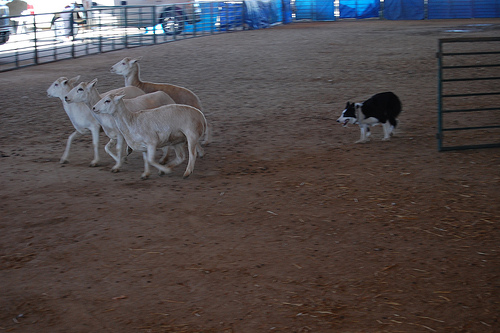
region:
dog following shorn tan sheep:
[40, 48, 405, 178]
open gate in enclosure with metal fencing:
[0, 0, 492, 155]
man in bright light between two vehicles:
[0, 0, 200, 70]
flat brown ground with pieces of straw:
[6, 15, 491, 322]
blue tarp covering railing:
[182, 0, 497, 35]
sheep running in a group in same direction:
[45, 50, 210, 175]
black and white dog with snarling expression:
[330, 85, 400, 145]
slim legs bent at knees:
[55, 126, 170, 177]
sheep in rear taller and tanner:
[45, 51, 206, 173]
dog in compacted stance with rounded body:
[335, 88, 403, 143]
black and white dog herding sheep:
[323, 86, 410, 153]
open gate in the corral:
[430, 29, 491, 114]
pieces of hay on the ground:
[336, 200, 405, 310]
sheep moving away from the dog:
[37, 51, 215, 188]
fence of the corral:
[21, 10, 169, 52]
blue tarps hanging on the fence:
[276, 3, 398, 15]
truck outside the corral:
[114, 0, 223, 32]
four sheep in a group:
[42, 52, 207, 168]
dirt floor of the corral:
[71, 202, 198, 305]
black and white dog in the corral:
[322, 85, 402, 147]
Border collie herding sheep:
[337, 91, 404, 145]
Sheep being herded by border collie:
[45, 55, 212, 178]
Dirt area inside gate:
[3, 73, 498, 332]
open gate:
[434, 35, 499, 160]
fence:
[0, 0, 493, 80]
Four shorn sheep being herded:
[44, 54, 211, 179]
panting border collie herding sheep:
[333, 88, 405, 144]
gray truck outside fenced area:
[54, 0, 207, 43]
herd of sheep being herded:
[40, 54, 210, 183]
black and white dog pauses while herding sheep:
[335, 90, 406, 145]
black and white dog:
[339, 89, 407, 144]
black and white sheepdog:
[337, 90, 407, 142]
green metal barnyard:
[0, 0, 254, 82]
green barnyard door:
[436, 32, 498, 152]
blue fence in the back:
[189, 0, 497, 21]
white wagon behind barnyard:
[86, 2, 209, 30]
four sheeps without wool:
[46, 55, 207, 177]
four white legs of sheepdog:
[356, 123, 395, 144]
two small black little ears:
[345, 100, 355, 110]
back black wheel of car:
[158, 7, 187, 38]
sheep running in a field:
[26, 26, 248, 236]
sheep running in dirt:
[42, 22, 284, 219]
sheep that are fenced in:
[29, 8, 271, 233]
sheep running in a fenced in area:
[24, 18, 249, 228]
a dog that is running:
[314, 68, 431, 186]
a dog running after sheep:
[77, 27, 422, 219]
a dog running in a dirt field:
[297, 52, 449, 192]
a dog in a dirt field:
[242, 23, 474, 247]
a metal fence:
[35, 9, 265, 84]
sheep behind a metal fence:
[34, 28, 425, 295]